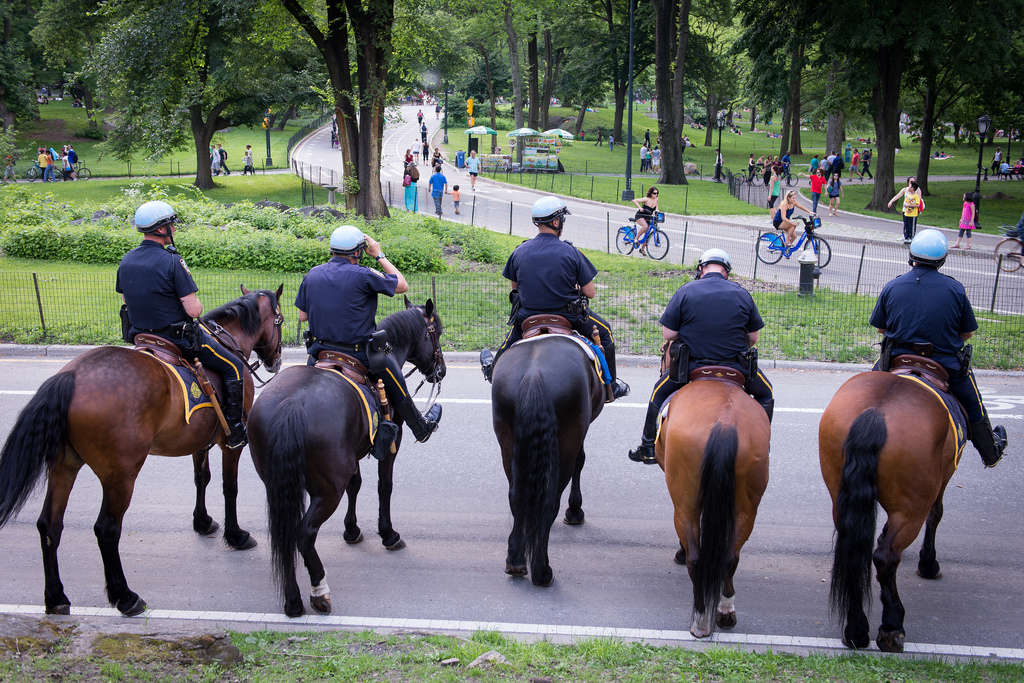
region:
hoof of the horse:
[55, 593, 82, 612]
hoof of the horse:
[121, 595, 150, 614]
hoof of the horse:
[193, 514, 214, 535]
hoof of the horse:
[277, 578, 300, 620]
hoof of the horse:
[313, 591, 334, 612]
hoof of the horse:
[492, 563, 519, 579]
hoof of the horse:
[531, 568, 555, 587]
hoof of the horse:
[569, 503, 595, 532]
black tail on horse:
[5, 369, 79, 526]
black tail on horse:
[256, 405, 327, 596]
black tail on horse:
[514, 364, 566, 567]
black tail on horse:
[700, 421, 746, 624]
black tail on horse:
[836, 397, 887, 650]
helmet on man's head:
[134, 192, 180, 240]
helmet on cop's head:
[328, 212, 368, 264]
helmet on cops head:
[512, 189, 579, 227]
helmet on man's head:
[907, 217, 953, 268]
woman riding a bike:
[612, 180, 688, 269]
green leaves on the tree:
[532, 51, 596, 118]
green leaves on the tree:
[836, 42, 912, 115]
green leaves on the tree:
[909, 25, 1011, 139]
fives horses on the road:
[12, 187, 980, 639]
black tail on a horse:
[691, 425, 762, 612]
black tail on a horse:
[821, 402, 885, 633]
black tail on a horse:
[499, 383, 553, 557]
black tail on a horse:
[254, 404, 322, 597]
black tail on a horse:
[2, 363, 88, 510]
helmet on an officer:
[527, 178, 569, 232]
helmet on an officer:
[906, 218, 965, 267]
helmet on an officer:
[325, 224, 365, 257]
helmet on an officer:
[131, 193, 180, 238]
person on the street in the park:
[397, 150, 414, 212]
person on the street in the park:
[428, 163, 451, 218]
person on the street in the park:
[441, 172, 458, 227]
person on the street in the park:
[456, 141, 479, 186]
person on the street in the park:
[630, 179, 660, 246]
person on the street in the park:
[801, 160, 818, 217]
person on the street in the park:
[886, 169, 921, 242]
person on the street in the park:
[947, 185, 979, 246]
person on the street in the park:
[844, 141, 864, 176]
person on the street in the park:
[735, 151, 759, 194]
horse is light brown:
[661, 338, 833, 674]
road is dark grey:
[397, 549, 514, 619]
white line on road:
[433, 355, 503, 460]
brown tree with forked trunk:
[275, 37, 421, 253]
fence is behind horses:
[35, 253, 116, 358]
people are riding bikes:
[438, 104, 888, 241]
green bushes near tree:
[40, 192, 437, 241]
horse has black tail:
[675, 452, 756, 618]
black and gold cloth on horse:
[310, 353, 459, 470]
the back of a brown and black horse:
[819, 375, 976, 655]